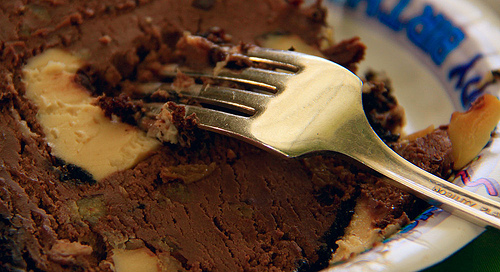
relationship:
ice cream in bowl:
[1, 1, 403, 271] [325, 0, 500, 272]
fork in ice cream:
[141, 44, 500, 234] [1, 1, 403, 271]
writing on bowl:
[348, 0, 466, 66] [325, 0, 500, 272]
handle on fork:
[360, 111, 499, 230] [141, 44, 500, 234]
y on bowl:
[446, 54, 484, 85] [325, 0, 500, 272]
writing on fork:
[432, 185, 476, 205] [141, 44, 500, 234]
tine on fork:
[140, 81, 271, 115] [141, 44, 500, 234]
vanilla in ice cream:
[25, 47, 166, 184] [1, 1, 403, 271]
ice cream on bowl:
[1, 1, 403, 271] [325, 0, 500, 272]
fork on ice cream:
[141, 44, 500, 234] [1, 1, 403, 271]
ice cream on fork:
[1, 1, 403, 271] [141, 44, 500, 234]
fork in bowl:
[141, 44, 500, 234] [325, 0, 500, 272]